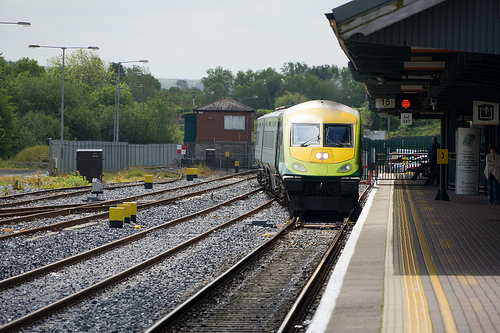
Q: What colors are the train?
A: Yellow and Green.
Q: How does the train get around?
A: Tracks.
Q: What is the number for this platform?
A: 15.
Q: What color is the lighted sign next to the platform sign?
A: Red.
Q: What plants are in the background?
A: Trees.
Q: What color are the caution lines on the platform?
A: Yellow.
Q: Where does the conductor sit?
A: In front.